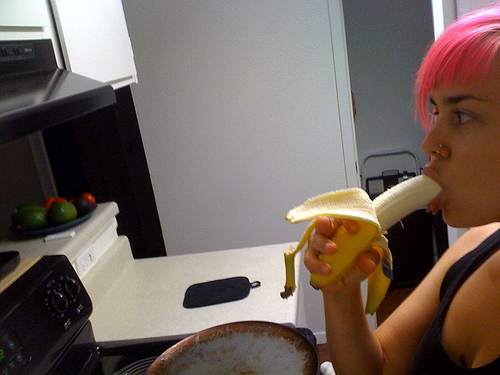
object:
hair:
[411, 6, 499, 134]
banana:
[280, 167, 443, 315]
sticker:
[381, 259, 393, 279]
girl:
[303, 3, 497, 374]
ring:
[436, 143, 442, 156]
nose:
[423, 115, 451, 160]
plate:
[144, 319, 319, 374]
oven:
[1, 251, 95, 375]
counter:
[87, 239, 304, 348]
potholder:
[181, 276, 262, 308]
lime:
[46, 202, 77, 224]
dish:
[7, 201, 104, 240]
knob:
[49, 288, 70, 315]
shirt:
[410, 225, 498, 375]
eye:
[452, 109, 481, 126]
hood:
[0, 37, 120, 196]